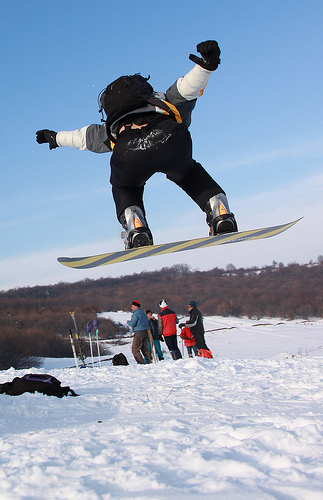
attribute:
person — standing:
[179, 301, 213, 359]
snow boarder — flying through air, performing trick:
[37, 41, 238, 251]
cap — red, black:
[133, 300, 141, 308]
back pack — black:
[99, 74, 178, 144]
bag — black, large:
[1, 373, 78, 397]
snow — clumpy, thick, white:
[1, 312, 322, 499]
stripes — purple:
[27, 373, 54, 383]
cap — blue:
[189, 300, 197, 308]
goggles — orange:
[188, 305, 193, 308]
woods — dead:
[1, 254, 322, 372]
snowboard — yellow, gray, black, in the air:
[57, 217, 304, 269]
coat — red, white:
[179, 328, 196, 348]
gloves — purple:
[86, 318, 99, 332]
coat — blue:
[127, 307, 149, 332]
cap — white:
[158, 299, 168, 308]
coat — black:
[185, 310, 205, 333]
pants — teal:
[144, 339, 162, 361]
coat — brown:
[147, 319, 164, 342]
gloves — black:
[37, 40, 222, 150]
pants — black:
[110, 126, 225, 225]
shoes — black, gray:
[120, 194, 239, 250]